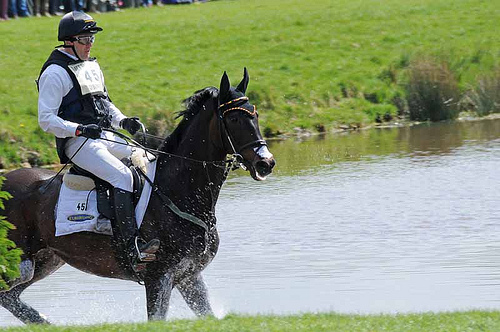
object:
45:
[81, 68, 106, 83]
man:
[33, 7, 168, 274]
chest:
[70, 62, 105, 87]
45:
[74, 200, 92, 212]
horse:
[0, 64, 282, 323]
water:
[0, 115, 499, 324]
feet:
[1, 13, 13, 24]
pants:
[62, 126, 143, 194]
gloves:
[75, 120, 101, 141]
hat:
[53, 9, 108, 66]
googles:
[67, 32, 98, 47]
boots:
[106, 185, 159, 273]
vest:
[33, 46, 118, 168]